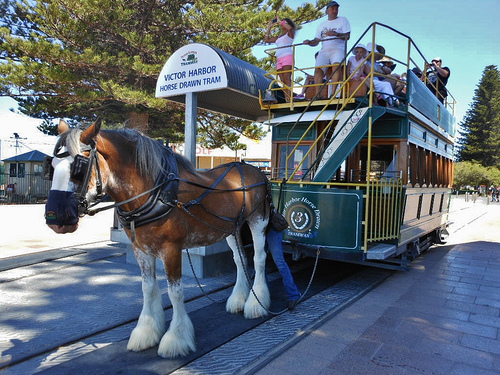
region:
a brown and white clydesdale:
[40, 114, 287, 364]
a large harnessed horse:
[37, 115, 294, 357]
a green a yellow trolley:
[247, 14, 464, 282]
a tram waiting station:
[145, 38, 272, 190]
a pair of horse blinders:
[42, 152, 97, 189]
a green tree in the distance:
[455, 52, 499, 161]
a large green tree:
[0, 0, 327, 149]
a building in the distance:
[0, 143, 57, 208]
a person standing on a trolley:
[308, 0, 348, 97]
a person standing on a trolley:
[255, 16, 297, 109]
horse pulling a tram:
[19, 22, 463, 362]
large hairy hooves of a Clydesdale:
[118, 292, 212, 359]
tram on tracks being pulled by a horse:
[260, 38, 476, 278]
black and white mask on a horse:
[39, 132, 95, 231]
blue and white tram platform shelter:
[150, 49, 256, 111]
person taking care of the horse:
[263, 209, 308, 316]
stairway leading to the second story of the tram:
[281, 65, 375, 190]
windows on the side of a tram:
[403, 137, 466, 216]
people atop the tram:
[267, 1, 354, 47]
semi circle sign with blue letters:
[145, 38, 235, 109]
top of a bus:
[399, 47, 435, 56]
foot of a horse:
[183, 331, 195, 340]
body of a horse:
[200, 197, 236, 216]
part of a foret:
[474, 153, 486, 170]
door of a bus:
[388, 188, 392, 193]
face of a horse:
[63, 173, 70, 210]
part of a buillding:
[23, 155, 30, 179]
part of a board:
[320, 207, 339, 229]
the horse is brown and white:
[35, 132, 340, 367]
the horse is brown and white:
[65, 135, 241, 328]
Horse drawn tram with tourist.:
[42, 3, 477, 359]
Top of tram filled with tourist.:
[252, 1, 472, 121]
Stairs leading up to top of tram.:
[276, 22, 411, 192]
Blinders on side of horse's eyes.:
[35, 150, 100, 180]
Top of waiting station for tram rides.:
[145, 27, 261, 117]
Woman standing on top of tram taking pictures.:
[258, 15, 310, 105]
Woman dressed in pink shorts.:
[268, 52, 300, 73]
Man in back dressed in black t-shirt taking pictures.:
[418, 53, 455, 101]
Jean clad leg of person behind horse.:
[267, 228, 319, 316]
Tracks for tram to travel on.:
[191, 286, 302, 373]